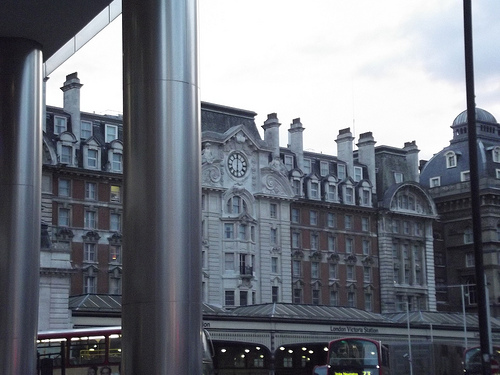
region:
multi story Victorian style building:
[52, 95, 494, 357]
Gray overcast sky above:
[209, 8, 498, 163]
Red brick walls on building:
[291, 201, 379, 298]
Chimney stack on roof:
[256, 110, 281, 170]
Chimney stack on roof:
[294, 118, 313, 174]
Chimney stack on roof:
[331, 128, 358, 181]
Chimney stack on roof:
[398, 126, 430, 186]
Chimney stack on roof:
[53, 68, 84, 123]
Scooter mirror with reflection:
[330, 329, 392, 366]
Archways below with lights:
[210, 334, 373, 368]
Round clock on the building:
[218, 143, 256, 185]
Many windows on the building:
[283, 173, 381, 309]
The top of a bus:
[319, 330, 399, 372]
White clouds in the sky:
[320, 6, 456, 101]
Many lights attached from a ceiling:
[218, 336, 331, 366]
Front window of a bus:
[321, 336, 386, 368]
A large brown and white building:
[31, 70, 498, 341]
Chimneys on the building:
[263, 107, 383, 172]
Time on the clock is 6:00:
[222, 148, 254, 183]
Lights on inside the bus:
[35, 328, 125, 347]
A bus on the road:
[23, 318, 223, 373]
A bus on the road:
[324, 332, 387, 374]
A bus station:
[72, 294, 499, 366]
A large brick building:
[39, 99, 444, 325]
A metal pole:
[111, 0, 206, 373]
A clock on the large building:
[210, 137, 266, 183]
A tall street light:
[386, 293, 427, 369]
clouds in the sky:
[41, 0, 441, 153]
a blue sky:
[432, 2, 498, 86]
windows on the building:
[288, 202, 384, 302]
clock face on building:
[225, 144, 250, 181]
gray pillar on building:
[117, 0, 202, 373]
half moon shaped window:
[384, 182, 438, 217]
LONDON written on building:
[331, 325, 347, 333]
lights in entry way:
[211, 340, 355, 372]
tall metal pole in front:
[401, 298, 421, 374]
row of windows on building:
[291, 208, 371, 232]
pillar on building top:
[260, 108, 282, 153]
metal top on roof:
[236, 311, 388, 321]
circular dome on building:
[448, 105, 499, 128]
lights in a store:
[214, 336, 334, 370]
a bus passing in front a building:
[309, 331, 474, 373]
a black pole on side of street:
[453, 1, 498, 364]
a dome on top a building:
[439, 94, 499, 139]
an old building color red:
[284, 127, 384, 314]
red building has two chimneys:
[288, 108, 362, 204]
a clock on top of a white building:
[223, 143, 254, 181]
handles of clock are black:
[217, 148, 257, 184]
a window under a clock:
[219, 179, 261, 227]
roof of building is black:
[202, 96, 273, 168]